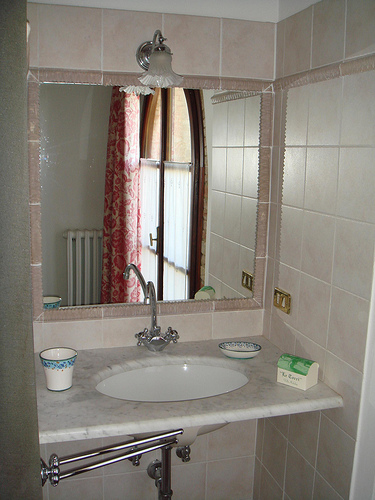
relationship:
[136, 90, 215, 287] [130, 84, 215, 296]
brown frame on arched window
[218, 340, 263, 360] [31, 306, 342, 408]
bowl on vanity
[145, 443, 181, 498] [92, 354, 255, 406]
pipes under sink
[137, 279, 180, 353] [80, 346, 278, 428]
faucet over sink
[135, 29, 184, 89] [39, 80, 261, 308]
lamp over mirror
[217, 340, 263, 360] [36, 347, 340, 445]
bowl on countertop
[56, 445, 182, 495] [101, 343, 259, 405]
silver piping for sink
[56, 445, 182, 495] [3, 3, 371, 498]
silver piping for bathroom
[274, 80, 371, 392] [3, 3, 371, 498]
tile of bathroom